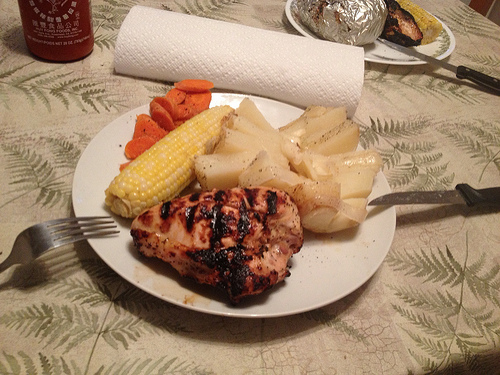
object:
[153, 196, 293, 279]
chicken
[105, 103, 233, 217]
corn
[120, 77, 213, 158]
carrots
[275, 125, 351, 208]
potato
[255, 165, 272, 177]
pepper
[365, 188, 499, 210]
knife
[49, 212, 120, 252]
fork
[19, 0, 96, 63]
sauce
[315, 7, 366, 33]
potato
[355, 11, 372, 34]
foil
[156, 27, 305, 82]
towel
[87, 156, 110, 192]
plate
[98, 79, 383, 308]
food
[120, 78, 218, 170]
vegetables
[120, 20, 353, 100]
towels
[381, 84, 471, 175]
table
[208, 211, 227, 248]
sauce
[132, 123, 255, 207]
meal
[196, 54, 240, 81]
lines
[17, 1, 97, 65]
bottle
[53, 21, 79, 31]
writting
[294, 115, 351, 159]
wedges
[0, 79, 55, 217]
tablecloth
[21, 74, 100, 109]
design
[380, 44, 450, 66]
plate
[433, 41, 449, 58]
design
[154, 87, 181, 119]
pile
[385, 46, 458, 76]
blade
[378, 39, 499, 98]
knife